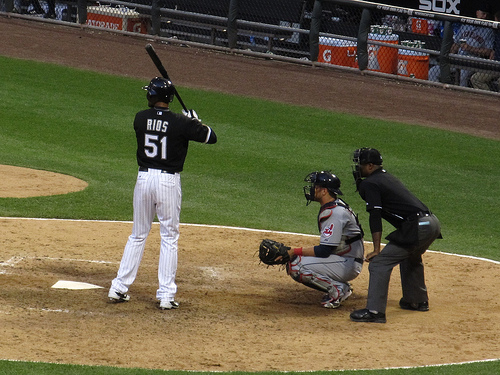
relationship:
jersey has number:
[132, 105, 206, 175] [141, 130, 179, 167]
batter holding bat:
[100, 27, 205, 326] [145, 40, 193, 120]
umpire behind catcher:
[350, 136, 442, 330] [259, 163, 358, 325]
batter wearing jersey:
[100, 27, 205, 326] [132, 105, 206, 175]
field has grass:
[6, 149, 298, 268] [232, 118, 296, 236]